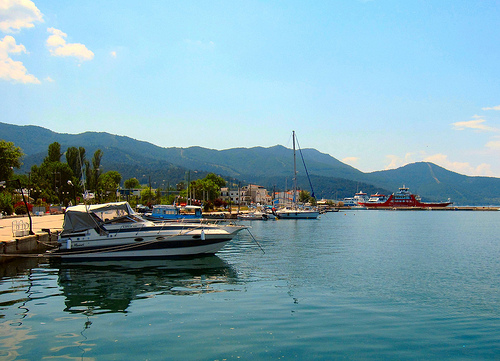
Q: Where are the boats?
A: In the water.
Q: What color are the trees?
A: Green.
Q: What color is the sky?
A: Blue.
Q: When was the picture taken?
A: In the daytime.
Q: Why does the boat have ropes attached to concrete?
A: It is docked.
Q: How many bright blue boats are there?
A: One.